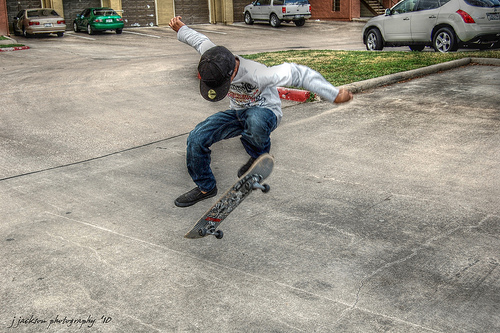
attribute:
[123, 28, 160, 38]
line — white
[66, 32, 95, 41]
line — white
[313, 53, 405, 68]
grass — green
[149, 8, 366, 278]
boy — young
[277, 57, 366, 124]
hand — bent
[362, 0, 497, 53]
car — white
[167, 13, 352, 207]
child — young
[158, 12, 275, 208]
child — using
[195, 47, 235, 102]
hat — black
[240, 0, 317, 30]
suv — parked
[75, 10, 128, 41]
car — green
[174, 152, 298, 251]
board — tilted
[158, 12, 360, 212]
boy — young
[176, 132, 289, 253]
skateboard — grey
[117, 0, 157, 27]
door — brown, garage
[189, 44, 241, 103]
cap — black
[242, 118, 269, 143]
knee — bent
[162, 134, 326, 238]
trick — skateboard